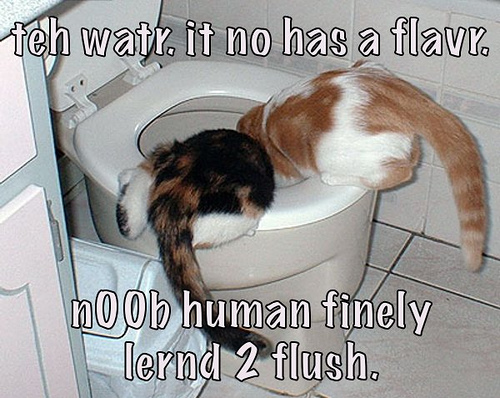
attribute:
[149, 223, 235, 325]
tail — black, brown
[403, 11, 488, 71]
birds — tiled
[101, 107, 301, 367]
cat — Calico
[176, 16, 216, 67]
word — white, outlined in black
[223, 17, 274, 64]
word — outlined in black, white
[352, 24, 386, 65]
word — outlined in black, white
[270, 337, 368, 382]
word — outlined in black, white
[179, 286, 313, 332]
word — outlined in black, white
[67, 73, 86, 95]
pieces — black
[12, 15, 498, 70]
meme text — misspelled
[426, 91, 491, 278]
tail — orange, white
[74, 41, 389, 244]
toilet cover — white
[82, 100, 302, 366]
cat — tan and white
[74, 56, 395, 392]
toilet bowl — white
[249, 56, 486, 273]
cat — Orange and white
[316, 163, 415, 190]
paws — white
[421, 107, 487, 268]
tail — brown, orange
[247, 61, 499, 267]
cat — tiled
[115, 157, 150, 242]
paw — white, black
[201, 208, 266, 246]
paw — black, white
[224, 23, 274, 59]
word — white, outlined in black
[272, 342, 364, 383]
word — white, outlined in black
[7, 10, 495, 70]
letters — outlined in black, white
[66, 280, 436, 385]
letters — white, outlined in black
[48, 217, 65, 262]
door hinges — white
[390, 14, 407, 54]
letters — white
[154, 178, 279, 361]
cat tail — orange, black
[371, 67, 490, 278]
cat tail — orange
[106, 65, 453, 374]
cat — black, brown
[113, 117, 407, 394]
toilet — white, porcelain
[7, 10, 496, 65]
words — misspelled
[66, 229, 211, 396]
trash can — white, small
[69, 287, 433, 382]
words — misspelled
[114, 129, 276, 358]
cat — white, black, orange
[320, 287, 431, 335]
word — outlined in black, white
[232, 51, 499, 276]
cat — orange, white